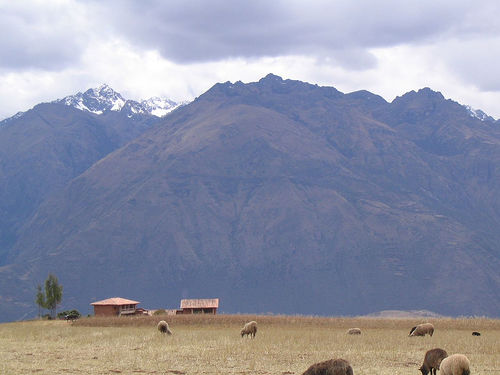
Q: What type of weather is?
A: It is cloudy.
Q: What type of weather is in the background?
A: It is cloudy.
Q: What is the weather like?
A: It is cloudy.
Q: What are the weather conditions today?
A: It is cloudy.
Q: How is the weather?
A: It is cloudy.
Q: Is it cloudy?
A: Yes, it is cloudy.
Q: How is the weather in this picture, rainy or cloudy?
A: It is cloudy.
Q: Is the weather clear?
A: No, it is cloudy.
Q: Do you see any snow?
A: Yes, there is snow.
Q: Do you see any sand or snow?
A: Yes, there is snow.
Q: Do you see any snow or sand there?
A: Yes, there is snow.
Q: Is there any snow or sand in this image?
A: Yes, there is snow.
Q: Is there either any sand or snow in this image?
A: Yes, there is snow.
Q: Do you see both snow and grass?
A: Yes, there are both snow and grass.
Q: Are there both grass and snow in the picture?
A: Yes, there are both snow and grass.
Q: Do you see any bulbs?
A: No, there are no bulbs.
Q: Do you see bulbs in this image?
A: No, there are no bulbs.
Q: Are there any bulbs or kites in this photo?
A: No, there are no bulbs or kites.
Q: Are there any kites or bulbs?
A: No, there are no bulbs or kites.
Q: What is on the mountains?
A: The snow is on the mountains.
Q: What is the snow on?
A: The snow is on the mountains.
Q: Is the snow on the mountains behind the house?
A: Yes, the snow is on the mountains.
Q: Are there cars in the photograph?
A: No, there are no cars.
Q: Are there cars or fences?
A: No, there are no cars or fences.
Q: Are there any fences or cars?
A: No, there are no cars or fences.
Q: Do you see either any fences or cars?
A: No, there are no cars or fences.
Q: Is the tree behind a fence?
A: No, the tree is behind the house.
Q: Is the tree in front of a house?
A: No, the tree is behind a house.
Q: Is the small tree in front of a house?
A: No, the tree is behind a house.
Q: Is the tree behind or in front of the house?
A: The tree is behind the house.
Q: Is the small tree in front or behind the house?
A: The tree is behind the house.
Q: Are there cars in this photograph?
A: No, there are no cars.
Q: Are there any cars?
A: No, there are no cars.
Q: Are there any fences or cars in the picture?
A: No, there are no cars or fences.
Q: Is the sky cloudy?
A: Yes, the sky is cloudy.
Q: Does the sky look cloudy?
A: Yes, the sky is cloudy.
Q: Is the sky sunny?
A: No, the sky is cloudy.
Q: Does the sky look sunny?
A: No, the sky is cloudy.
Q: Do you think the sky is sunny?
A: No, the sky is cloudy.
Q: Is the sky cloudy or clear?
A: The sky is cloudy.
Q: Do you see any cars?
A: No, there are no cars.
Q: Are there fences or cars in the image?
A: No, there are no cars or fences.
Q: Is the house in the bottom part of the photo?
A: Yes, the house is in the bottom of the image.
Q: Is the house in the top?
A: No, the house is in the bottom of the image.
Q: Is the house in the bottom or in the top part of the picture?
A: The house is in the bottom of the image.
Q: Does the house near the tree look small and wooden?
A: Yes, the house is small and wooden.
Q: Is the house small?
A: Yes, the house is small.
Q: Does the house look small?
A: Yes, the house is small.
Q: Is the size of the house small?
A: Yes, the house is small.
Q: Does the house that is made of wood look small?
A: Yes, the house is small.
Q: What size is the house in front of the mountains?
A: The house is small.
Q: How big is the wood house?
A: The house is small.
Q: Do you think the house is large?
A: No, the house is small.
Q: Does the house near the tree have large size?
A: No, the house is small.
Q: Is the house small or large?
A: The house is small.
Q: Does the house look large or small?
A: The house is small.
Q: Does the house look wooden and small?
A: Yes, the house is wooden and small.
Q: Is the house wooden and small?
A: Yes, the house is wooden and small.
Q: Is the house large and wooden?
A: No, the house is wooden but small.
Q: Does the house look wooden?
A: Yes, the house is wooden.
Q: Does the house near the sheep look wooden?
A: Yes, the house is wooden.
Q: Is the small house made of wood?
A: Yes, the house is made of wood.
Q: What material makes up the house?
A: The house is made of wood.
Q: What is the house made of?
A: The house is made of wood.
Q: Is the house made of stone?
A: No, the house is made of wood.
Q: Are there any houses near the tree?
A: Yes, there is a house near the tree.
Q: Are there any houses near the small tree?
A: Yes, there is a house near the tree.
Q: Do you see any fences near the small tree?
A: No, there is a house near the tree.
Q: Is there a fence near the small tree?
A: No, there is a house near the tree.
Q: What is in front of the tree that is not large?
A: The house is in front of the tree.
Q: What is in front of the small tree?
A: The house is in front of the tree.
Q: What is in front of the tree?
A: The house is in front of the tree.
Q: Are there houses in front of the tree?
A: Yes, there is a house in front of the tree.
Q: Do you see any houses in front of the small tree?
A: Yes, there is a house in front of the tree.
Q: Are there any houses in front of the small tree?
A: Yes, there is a house in front of the tree.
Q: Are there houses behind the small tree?
A: No, the house is in front of the tree.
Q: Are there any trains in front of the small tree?
A: No, there is a house in front of the tree.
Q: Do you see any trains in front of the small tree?
A: No, there is a house in front of the tree.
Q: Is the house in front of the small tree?
A: Yes, the house is in front of the tree.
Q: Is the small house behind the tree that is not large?
A: No, the house is in front of the tree.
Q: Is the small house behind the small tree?
A: No, the house is in front of the tree.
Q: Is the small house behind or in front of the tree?
A: The house is in front of the tree.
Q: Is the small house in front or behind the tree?
A: The house is in front of the tree.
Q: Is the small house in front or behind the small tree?
A: The house is in front of the tree.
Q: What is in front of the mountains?
A: The house is in front of the mountains.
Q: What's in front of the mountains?
A: The house is in front of the mountains.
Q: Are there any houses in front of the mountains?
A: Yes, there is a house in front of the mountains.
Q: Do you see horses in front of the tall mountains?
A: No, there is a house in front of the mountains.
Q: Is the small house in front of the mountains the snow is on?
A: Yes, the house is in front of the mountains.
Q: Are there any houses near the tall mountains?
A: Yes, there is a house near the mountains.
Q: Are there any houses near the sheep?
A: Yes, there is a house near the sheep.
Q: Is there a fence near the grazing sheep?
A: No, there is a house near the sheep.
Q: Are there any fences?
A: No, there are no fences.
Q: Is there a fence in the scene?
A: No, there are no fences.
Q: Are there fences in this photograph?
A: No, there are no fences.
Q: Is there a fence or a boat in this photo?
A: No, there are no fences or boats.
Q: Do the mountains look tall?
A: Yes, the mountains are tall.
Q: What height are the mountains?
A: The mountains are tall.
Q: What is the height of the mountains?
A: The mountains are tall.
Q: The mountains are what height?
A: The mountains are tall.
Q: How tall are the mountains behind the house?
A: The mountains are tall.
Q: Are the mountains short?
A: No, the mountains are tall.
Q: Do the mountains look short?
A: No, the mountains are tall.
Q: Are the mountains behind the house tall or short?
A: The mountains are tall.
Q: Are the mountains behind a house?
A: Yes, the mountains are behind a house.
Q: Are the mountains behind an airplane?
A: No, the mountains are behind a house.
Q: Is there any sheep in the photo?
A: Yes, there is a sheep.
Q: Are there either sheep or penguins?
A: Yes, there is a sheep.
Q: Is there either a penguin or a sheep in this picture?
A: Yes, there is a sheep.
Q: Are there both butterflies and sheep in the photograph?
A: No, there is a sheep but no butterflies.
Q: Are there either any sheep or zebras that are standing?
A: Yes, the sheep is standing.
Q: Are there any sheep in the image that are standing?
A: Yes, there is a sheep that is standing.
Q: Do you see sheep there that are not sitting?
A: Yes, there is a sheep that is standing .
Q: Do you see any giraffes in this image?
A: No, there are no giraffes.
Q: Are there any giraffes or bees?
A: No, there are no giraffes or bees.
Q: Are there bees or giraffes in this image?
A: No, there are no giraffes or bees.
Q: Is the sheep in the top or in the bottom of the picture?
A: The sheep is in the bottom of the image.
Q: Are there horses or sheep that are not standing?
A: No, there is a sheep but it is standing.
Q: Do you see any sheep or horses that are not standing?
A: No, there is a sheep but it is standing.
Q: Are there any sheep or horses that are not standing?
A: No, there is a sheep but it is standing.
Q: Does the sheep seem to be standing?
A: Yes, the sheep is standing.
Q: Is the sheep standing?
A: Yes, the sheep is standing.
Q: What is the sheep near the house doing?
A: The sheep is standing.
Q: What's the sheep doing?
A: The sheep is standing.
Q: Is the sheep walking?
A: No, the sheep is standing.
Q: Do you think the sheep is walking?
A: No, the sheep is standing.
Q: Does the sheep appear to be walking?
A: No, the sheep is standing.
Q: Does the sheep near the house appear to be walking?
A: No, the sheep is standing.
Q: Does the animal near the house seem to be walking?
A: No, the sheep is standing.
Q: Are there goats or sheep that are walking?
A: No, there is a sheep but it is standing.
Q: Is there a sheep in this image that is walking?
A: No, there is a sheep but it is standing.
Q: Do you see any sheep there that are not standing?
A: No, there is a sheep but it is standing.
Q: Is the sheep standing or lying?
A: The sheep is standing.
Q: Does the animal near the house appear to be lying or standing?
A: The sheep is standing.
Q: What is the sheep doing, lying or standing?
A: The sheep is standing.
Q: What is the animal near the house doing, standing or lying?
A: The sheep is standing.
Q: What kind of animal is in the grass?
A: The animal is a sheep.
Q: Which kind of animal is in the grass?
A: The animal is a sheep.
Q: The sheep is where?
A: The sheep is in the grass.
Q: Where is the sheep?
A: The sheep is in the grass.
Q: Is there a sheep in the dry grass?
A: Yes, there is a sheep in the grass.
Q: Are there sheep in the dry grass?
A: Yes, there is a sheep in the grass.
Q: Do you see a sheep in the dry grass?
A: Yes, there is a sheep in the grass.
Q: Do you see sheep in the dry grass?
A: Yes, there is a sheep in the grass.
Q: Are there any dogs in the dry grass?
A: No, there is a sheep in the grass.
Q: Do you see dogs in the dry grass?
A: No, there is a sheep in the grass.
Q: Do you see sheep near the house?
A: Yes, there is a sheep near the house.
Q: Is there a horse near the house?
A: No, there is a sheep near the house.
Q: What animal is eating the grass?
A: The sheep is eating the grass.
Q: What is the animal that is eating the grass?
A: The animal is a sheep.